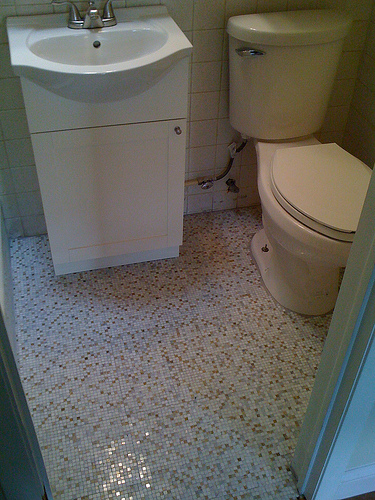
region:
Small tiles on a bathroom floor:
[61, 391, 95, 402]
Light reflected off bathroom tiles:
[91, 456, 157, 489]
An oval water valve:
[200, 181, 214, 189]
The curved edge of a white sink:
[54, 71, 153, 95]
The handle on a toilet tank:
[241, 46, 265, 56]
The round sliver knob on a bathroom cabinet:
[172, 127, 183, 137]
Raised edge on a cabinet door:
[161, 220, 181, 244]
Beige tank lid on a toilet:
[226, 22, 354, 40]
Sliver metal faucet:
[85, 6, 103, 22]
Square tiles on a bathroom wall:
[193, 116, 219, 147]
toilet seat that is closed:
[276, 148, 374, 221]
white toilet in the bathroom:
[220, 18, 371, 308]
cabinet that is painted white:
[35, 136, 190, 243]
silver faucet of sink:
[46, 1, 131, 35]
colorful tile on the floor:
[53, 338, 188, 427]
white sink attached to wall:
[14, 28, 199, 75]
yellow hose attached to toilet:
[182, 179, 224, 188]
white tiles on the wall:
[196, 89, 218, 132]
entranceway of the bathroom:
[48, 463, 318, 497]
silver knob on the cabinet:
[170, 127, 186, 137]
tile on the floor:
[140, 292, 196, 327]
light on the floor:
[97, 451, 150, 491]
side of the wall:
[297, 456, 335, 493]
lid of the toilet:
[294, 180, 340, 214]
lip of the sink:
[57, 46, 124, 66]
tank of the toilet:
[250, 12, 340, 43]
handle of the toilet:
[220, 41, 265, 60]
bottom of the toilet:
[260, 273, 325, 316]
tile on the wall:
[195, 120, 214, 159]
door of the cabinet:
[87, 187, 172, 232]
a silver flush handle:
[233, 47, 266, 58]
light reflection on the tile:
[102, 437, 150, 494]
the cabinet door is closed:
[40, 116, 188, 260]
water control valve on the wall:
[227, 185, 239, 196]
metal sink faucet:
[57, 2, 119, 27]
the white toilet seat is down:
[271, 137, 370, 240]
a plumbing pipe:
[184, 141, 246, 187]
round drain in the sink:
[91, 40, 100, 47]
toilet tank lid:
[231, 8, 351, 39]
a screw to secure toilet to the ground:
[261, 243, 268, 252]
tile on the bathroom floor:
[26, 280, 306, 490]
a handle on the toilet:
[239, 47, 264, 54]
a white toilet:
[230, 11, 371, 306]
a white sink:
[15, 14, 193, 86]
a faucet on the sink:
[53, 0, 123, 24]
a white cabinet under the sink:
[35, 91, 201, 271]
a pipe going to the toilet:
[194, 141, 242, 194]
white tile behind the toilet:
[192, 15, 228, 163]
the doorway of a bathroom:
[319, 252, 359, 466]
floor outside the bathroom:
[352, 489, 374, 496]